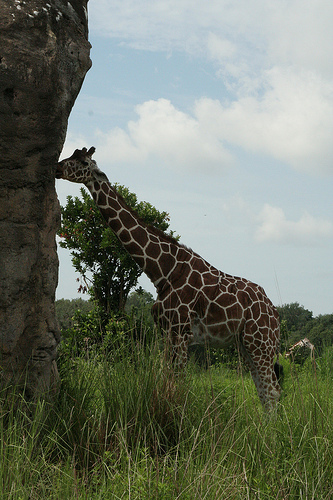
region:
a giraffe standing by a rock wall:
[53, 144, 294, 426]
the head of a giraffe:
[52, 140, 101, 187]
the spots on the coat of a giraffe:
[190, 280, 250, 328]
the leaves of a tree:
[66, 209, 97, 247]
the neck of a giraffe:
[93, 180, 182, 280]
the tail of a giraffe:
[269, 329, 286, 393]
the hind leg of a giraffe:
[242, 327, 282, 424]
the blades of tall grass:
[70, 327, 185, 471]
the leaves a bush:
[59, 304, 106, 353]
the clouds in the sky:
[156, 47, 282, 190]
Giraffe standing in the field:
[43, 132, 282, 397]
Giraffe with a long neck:
[86, 183, 193, 293]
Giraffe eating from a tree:
[49, 144, 107, 207]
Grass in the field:
[78, 330, 192, 453]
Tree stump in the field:
[283, 325, 317, 371]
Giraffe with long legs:
[242, 300, 290, 429]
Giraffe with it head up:
[56, 145, 107, 195]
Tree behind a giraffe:
[76, 198, 134, 309]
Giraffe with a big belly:
[184, 291, 244, 346]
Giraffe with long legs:
[139, 280, 207, 431]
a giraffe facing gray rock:
[56, 144, 286, 435]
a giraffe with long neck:
[82, 184, 191, 296]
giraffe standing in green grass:
[0, 346, 332, 499]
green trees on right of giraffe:
[56, 182, 182, 374]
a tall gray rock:
[0, 0, 93, 462]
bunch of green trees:
[55, 286, 332, 345]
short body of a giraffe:
[150, 276, 282, 349]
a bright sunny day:
[54, 0, 332, 317]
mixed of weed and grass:
[0, 339, 332, 499]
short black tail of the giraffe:
[272, 346, 285, 391]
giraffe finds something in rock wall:
[39, 141, 283, 446]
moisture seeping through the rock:
[2, 57, 58, 386]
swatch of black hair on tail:
[268, 361, 294, 398]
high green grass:
[1, 323, 332, 499]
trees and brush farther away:
[41, 276, 332, 355]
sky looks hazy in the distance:
[90, 10, 323, 315]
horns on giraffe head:
[74, 141, 98, 155]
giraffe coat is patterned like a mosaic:
[82, 171, 285, 366]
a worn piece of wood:
[282, 331, 322, 391]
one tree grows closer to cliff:
[58, 189, 172, 365]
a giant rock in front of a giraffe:
[0, 0, 91, 407]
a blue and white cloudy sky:
[54, 1, 331, 316]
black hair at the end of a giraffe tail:
[274, 361, 284, 390]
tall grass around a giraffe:
[1, 336, 332, 499]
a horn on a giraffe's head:
[89, 144, 96, 153]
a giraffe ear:
[92, 169, 108, 184]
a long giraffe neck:
[87, 179, 179, 291]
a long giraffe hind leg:
[242, 329, 284, 419]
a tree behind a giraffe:
[61, 179, 176, 351]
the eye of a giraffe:
[81, 159, 88, 166]